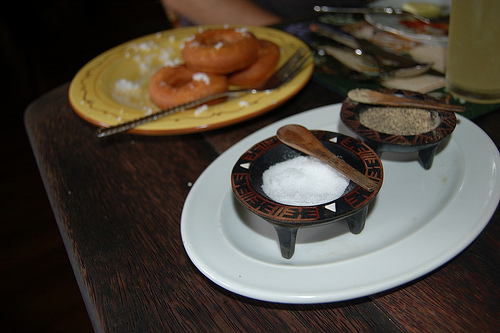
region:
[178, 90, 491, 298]
white plate is oval in shape.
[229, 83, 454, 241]
Two bowls are in plate.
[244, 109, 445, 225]
Bowls are brown color.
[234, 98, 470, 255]
Bowls are made of wood.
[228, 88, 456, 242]
Salt and pepper are in bowl.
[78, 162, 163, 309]
Table is brown color.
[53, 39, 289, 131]
Plate is orange color.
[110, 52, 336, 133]
Fork is in plate.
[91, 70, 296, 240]
Plates are in table.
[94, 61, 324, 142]
Fork is silver color.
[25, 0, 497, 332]
a very dark wooden table with visible wood grain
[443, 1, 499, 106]
a glass holding yellow liquid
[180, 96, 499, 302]
oval white plate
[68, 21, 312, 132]
oval yellow plate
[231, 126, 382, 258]
round wooden salt server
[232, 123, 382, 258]
small flat wooden spoon on salt server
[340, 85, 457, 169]
a pepper server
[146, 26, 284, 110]
three plain doughnuts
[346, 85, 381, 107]
pepper traces left on spoon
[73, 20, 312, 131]
powdery white substance on plate and partially on doughnuts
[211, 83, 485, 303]
Plate is oval shape.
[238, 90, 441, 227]
two bowl are in the plate.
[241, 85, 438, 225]
Bowls are made up of wood.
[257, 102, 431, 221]
Salt and pepper are in the bowl.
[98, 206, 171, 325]
Table is brown color.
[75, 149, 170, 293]
table is made of wood.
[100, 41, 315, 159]
Fork is in the plate.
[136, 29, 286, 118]
Donuts are in plate.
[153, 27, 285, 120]
three mini brown donuts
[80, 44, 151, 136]
the plate is yellow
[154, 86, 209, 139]
the plate is yellow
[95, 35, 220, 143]
the plate is yellow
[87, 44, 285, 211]
the plate is yellow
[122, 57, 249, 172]
the plate is yellow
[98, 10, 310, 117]
three donuts on plate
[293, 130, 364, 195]
wooden spoon on dish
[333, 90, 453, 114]
wooden spoon on dish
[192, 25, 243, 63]
donut on a plate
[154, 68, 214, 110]
donut on a plate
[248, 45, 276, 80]
donut on a plate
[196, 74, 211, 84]
sugar on the donut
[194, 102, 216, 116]
sugar on the donut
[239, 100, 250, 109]
sugar on the donut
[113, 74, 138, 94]
sugar on the donut